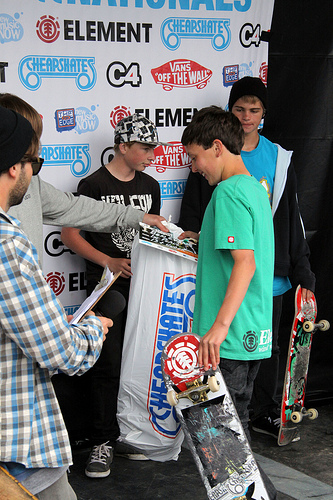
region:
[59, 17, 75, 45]
The letter is black.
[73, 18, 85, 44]
The letter is black.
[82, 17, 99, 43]
The letter is black.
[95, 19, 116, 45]
The letter is black.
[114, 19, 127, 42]
The letter is black.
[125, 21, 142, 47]
The letter is black.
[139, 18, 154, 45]
The letter is black.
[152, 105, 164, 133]
The letter is black.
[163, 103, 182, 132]
The letter is black.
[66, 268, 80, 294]
The letter is black.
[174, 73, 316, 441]
Boy wearing a black cap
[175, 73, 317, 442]
Boy wearing a blue shirt and black sweatshirt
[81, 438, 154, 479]
Gray skater shoes with white soles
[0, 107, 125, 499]
Man holding a microphone and clipboard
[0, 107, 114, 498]
Man wearing a white and blue plaid shirt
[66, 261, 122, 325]
Clipboard with white paper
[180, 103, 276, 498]
Boy wearing an oversized green shirt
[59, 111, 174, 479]
Boy wearing black clothing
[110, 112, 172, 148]
Black and white hat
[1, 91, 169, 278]
Person wearing a gray shirt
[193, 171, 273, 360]
bright green t-shirt with black and white writing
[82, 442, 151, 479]
grey sneakers with white laces and soles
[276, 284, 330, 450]
bottom of red skate board with green and black designs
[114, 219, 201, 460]
large white plastic shopping bag with blue writing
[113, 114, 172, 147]
black and white color blocked hat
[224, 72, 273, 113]
black knit skull cap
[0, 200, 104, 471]
blue white and grey plaid shirt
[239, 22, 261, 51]
large black and white C4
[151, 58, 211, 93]
bright red and white advertisement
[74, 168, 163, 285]
black and white tshirt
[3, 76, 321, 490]
several people at a skateboarding event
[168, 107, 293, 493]
a boy holding a skateboard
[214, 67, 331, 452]
a boy holding a skateboard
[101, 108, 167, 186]
a boy wearing a black and white hat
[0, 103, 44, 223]
a man wearing a black cap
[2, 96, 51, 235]
a man wearing sunglasses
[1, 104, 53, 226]
a man with a beard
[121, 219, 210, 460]
a long plastic bag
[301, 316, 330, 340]
the wheels of a skateboard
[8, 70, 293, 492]
several people at a skateboarding event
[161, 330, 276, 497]
a wooden skateboard held by a boy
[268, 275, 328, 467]
a wooden skateboard held by a boy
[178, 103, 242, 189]
the head of a boy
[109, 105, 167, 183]
the head of a boy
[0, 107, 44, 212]
the head of a man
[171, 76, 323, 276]
a boy wearing a gray jacket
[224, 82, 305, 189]
a boy wearing a blue t-shirt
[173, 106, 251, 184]
the face of a boy smiling